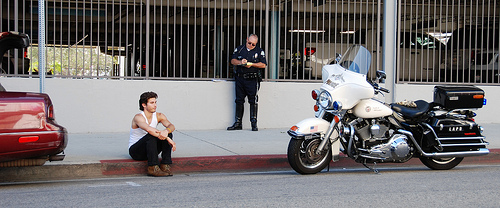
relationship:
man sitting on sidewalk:
[128, 88, 184, 182] [81, 112, 310, 161]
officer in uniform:
[236, 29, 262, 60] [228, 41, 268, 131]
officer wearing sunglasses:
[236, 29, 262, 60] [244, 40, 257, 48]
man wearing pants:
[128, 88, 184, 182] [122, 129, 181, 169]